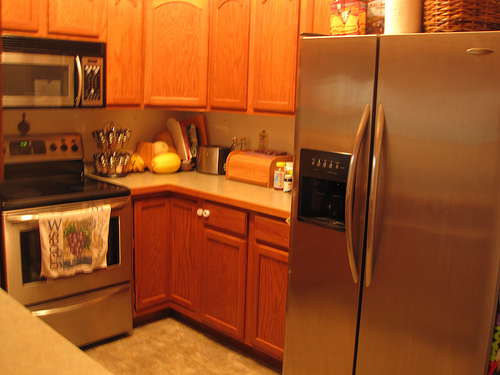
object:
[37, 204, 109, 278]
towel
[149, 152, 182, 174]
fruit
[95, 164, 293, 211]
counter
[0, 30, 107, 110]
microwave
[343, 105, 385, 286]
handles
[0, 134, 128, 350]
oven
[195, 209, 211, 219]
cupboard handles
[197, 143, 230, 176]
toaster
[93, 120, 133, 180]
spice rack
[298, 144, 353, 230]
ice &water dispenser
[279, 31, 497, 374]
fridge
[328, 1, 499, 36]
items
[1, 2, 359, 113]
cabinets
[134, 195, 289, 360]
cupboards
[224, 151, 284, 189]
bread box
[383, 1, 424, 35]
paper towel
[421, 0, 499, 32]
basket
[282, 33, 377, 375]
door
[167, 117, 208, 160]
papers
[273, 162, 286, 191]
bottles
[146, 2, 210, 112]
cabinet doors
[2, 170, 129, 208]
top of stove